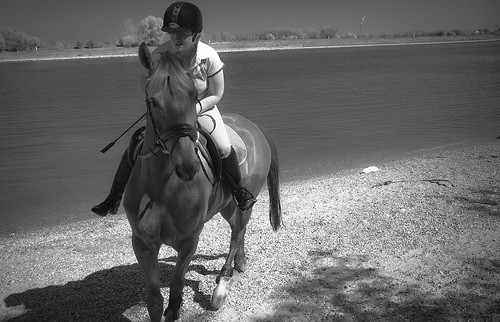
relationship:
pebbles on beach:
[314, 168, 414, 203] [13, 178, 105, 278]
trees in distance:
[119, 11, 165, 55] [2, 15, 98, 53]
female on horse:
[138, 6, 251, 133] [138, 65, 219, 272]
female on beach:
[138, 6, 251, 133] [13, 178, 105, 278]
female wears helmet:
[138, 6, 251, 133] [150, 1, 211, 66]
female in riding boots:
[138, 6, 251, 133] [103, 134, 140, 224]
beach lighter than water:
[13, 178, 105, 278] [287, 71, 416, 142]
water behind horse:
[287, 71, 416, 142] [138, 65, 219, 272]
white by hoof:
[211, 276, 238, 297] [212, 293, 245, 316]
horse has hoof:
[138, 65, 219, 272] [212, 293, 245, 316]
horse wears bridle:
[138, 65, 219, 272] [145, 112, 210, 149]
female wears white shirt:
[138, 6, 251, 133] [157, 37, 234, 68]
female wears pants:
[138, 6, 251, 133] [188, 102, 240, 163]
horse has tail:
[138, 65, 219, 272] [257, 133, 292, 227]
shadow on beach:
[9, 251, 201, 314] [13, 178, 105, 278]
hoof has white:
[212, 293, 245, 316] [211, 276, 238, 297]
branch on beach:
[369, 178, 455, 192] [13, 178, 105, 278]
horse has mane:
[138, 65, 219, 272] [145, 34, 195, 103]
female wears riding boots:
[138, 6, 251, 133] [222, 142, 255, 202]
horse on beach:
[138, 65, 219, 272] [13, 178, 105, 278]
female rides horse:
[138, 6, 251, 133] [138, 65, 219, 272]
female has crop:
[138, 6, 251, 133] [82, 108, 157, 146]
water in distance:
[287, 71, 416, 142] [2, 15, 98, 53]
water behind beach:
[287, 71, 416, 142] [13, 178, 105, 278]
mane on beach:
[145, 34, 195, 103] [13, 178, 105, 278]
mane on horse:
[145, 34, 195, 103] [138, 65, 219, 272]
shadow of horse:
[9, 251, 201, 314] [138, 65, 219, 272]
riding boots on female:
[222, 142, 255, 202] [138, 6, 251, 133]